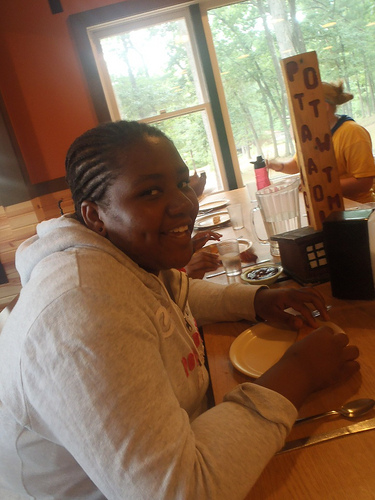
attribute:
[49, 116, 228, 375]
girl — eating, watching, looking, smiling, black, laughing, close, here, heavy, bigger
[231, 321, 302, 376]
plate — round, white, water, close, here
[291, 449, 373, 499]
table — wood, wooden, close, here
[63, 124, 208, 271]
person — smiling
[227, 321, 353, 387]
dish — white, empty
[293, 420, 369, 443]
knife — silver, butter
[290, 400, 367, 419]
spoon — silver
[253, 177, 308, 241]
pitcher — clear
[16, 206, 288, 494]
shirt — long sleeved, gray, sweat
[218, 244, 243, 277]
cup — clear